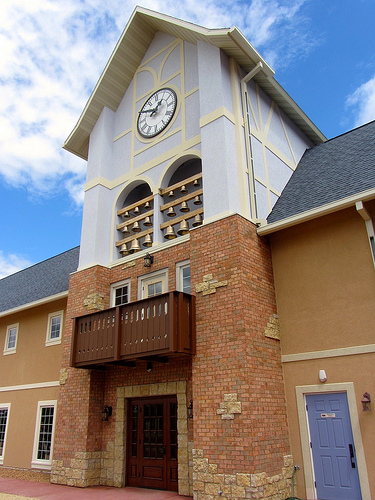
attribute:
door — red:
[122, 393, 177, 490]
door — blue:
[303, 390, 361, 499]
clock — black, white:
[133, 87, 177, 138]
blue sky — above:
[302, 16, 350, 90]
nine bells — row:
[114, 176, 156, 256]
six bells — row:
[112, 217, 161, 262]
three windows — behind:
[105, 258, 202, 311]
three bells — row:
[161, 176, 210, 197]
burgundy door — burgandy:
[124, 400, 177, 488]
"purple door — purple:
[295, 385, 361, 498]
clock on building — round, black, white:
[127, 79, 188, 143]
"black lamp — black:
[98, 401, 119, 425]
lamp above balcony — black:
[134, 251, 160, 270]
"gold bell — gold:
[141, 213, 158, 229]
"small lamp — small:
[359, 387, 370, 412]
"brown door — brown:
[125, 399, 177, 494]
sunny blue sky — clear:
[279, 9, 365, 81]